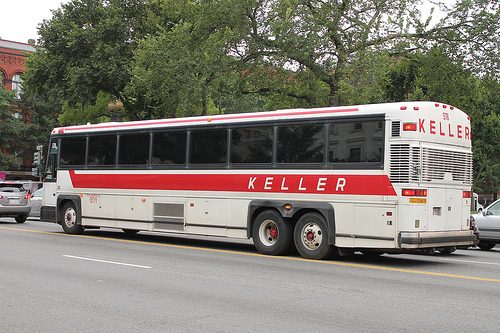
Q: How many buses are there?
A: One.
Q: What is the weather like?
A: Sunny.